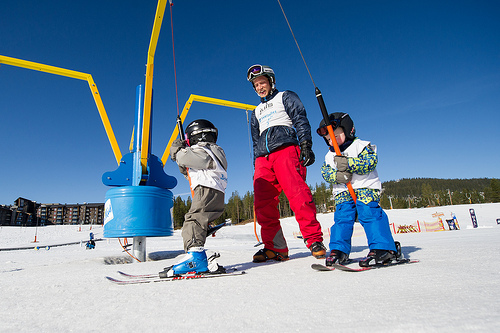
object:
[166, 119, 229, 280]
boy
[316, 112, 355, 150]
helmet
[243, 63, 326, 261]
man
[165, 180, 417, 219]
trees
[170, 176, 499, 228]
mountain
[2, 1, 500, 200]
blue sky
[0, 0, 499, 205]
sky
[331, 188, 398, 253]
blue pants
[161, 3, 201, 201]
pole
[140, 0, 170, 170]
pole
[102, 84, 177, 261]
base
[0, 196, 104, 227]
building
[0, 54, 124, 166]
pole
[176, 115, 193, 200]
pole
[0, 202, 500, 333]
mountain top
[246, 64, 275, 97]
helmets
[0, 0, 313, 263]
ride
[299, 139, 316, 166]
glove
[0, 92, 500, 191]
cloud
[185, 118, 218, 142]
helmet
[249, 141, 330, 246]
pants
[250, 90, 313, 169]
jacket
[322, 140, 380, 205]
jacket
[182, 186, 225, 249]
pants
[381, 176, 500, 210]
mountains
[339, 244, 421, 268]
shadows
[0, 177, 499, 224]
back ground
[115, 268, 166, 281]
ski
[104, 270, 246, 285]
ski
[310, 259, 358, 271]
ski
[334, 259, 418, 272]
ski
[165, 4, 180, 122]
wire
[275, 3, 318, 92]
wire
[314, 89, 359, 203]
pole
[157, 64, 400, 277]
family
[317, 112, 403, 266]
boy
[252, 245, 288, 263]
shoe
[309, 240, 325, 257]
shoe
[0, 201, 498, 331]
slope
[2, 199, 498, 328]
snow